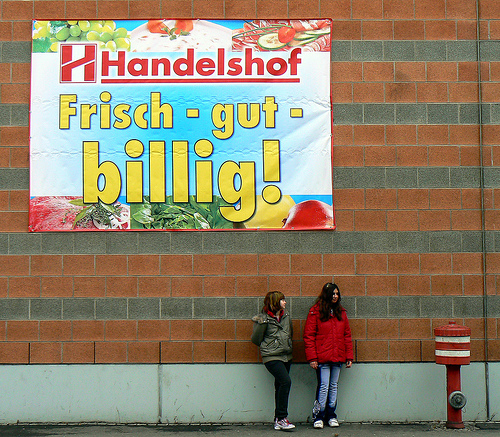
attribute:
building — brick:
[0, 2, 498, 379]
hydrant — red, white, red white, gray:
[435, 317, 476, 432]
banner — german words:
[24, 12, 342, 235]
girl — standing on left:
[249, 289, 302, 434]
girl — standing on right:
[308, 280, 356, 426]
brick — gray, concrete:
[22, 0, 339, 22]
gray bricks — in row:
[3, 232, 499, 257]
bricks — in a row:
[2, 256, 496, 276]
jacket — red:
[307, 307, 359, 367]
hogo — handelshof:
[58, 40, 99, 88]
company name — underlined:
[100, 44, 303, 88]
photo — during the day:
[1, 1, 500, 437]